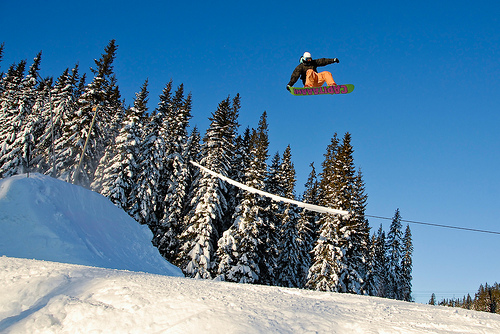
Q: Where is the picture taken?
A: Ski slope.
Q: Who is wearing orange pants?
A: The snowboarder.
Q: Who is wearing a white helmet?
A: The snowboarder.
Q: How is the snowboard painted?
A: Pink graffiti with green background.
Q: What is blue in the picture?
A: The sky.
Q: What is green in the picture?
A: The trees.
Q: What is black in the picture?
A: The snowboarder's jacket.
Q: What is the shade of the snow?
A: White.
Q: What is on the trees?
A: Snow.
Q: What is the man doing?
A: Snowboarding.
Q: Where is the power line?
A: In front of the trees.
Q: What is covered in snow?
A: Pine tree.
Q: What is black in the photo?
A: The man's jacket.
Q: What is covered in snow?
A: The green trees.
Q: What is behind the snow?
A: A group of trees.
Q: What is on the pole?
A: A wire.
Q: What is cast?
A: Shadow.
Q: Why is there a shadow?
A: Light.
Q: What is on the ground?
A: Snow.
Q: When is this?
A: Daytime.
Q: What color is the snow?
A: White.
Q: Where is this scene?
A: At a ski resort.